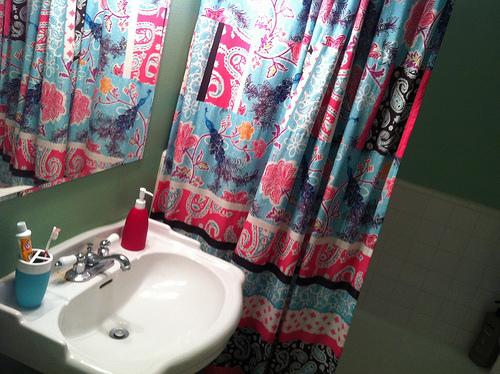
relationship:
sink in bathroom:
[1, 215, 248, 372] [0, 3, 497, 372]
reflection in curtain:
[1, 0, 169, 181] [177, 0, 452, 365]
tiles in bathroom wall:
[370, 178, 495, 348] [364, 3, 499, 342]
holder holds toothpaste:
[11, 212, 62, 324] [10, 214, 36, 260]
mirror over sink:
[0, 1, 169, 197] [1, 215, 248, 372]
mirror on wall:
[2, 1, 173, 191] [2, 0, 202, 270]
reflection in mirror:
[1, 5, 134, 150] [2, 1, 173, 191]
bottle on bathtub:
[467, 299, 499, 372] [324, 307, 472, 368]